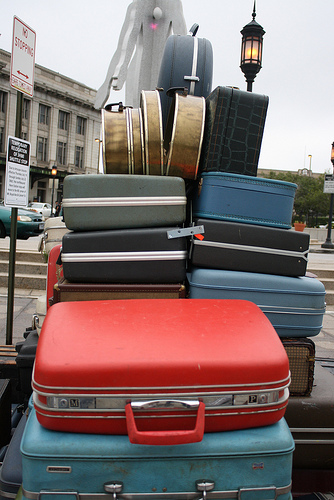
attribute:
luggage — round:
[202, 84, 275, 171]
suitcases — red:
[28, 150, 331, 428]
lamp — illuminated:
[238, 5, 265, 91]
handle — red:
[122, 396, 208, 448]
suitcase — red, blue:
[27, 295, 292, 446]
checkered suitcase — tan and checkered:
[277, 334, 317, 397]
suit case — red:
[22, 287, 281, 418]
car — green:
[0, 203, 37, 244]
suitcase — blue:
[18, 389, 296, 498]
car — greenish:
[0, 201, 47, 237]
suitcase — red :
[0, 276, 318, 446]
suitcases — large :
[0, 83, 324, 488]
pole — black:
[6, 202, 15, 349]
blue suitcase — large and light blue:
[189, 168, 300, 231]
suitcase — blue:
[13, 407, 305, 499]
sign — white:
[8, 13, 52, 152]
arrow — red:
[10, 61, 34, 77]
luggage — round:
[97, 99, 147, 173]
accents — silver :
[47, 393, 286, 410]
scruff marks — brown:
[24, 432, 286, 490]